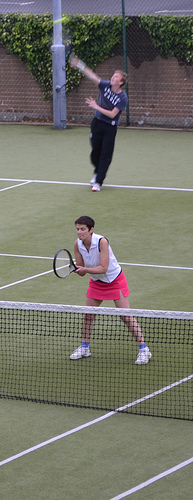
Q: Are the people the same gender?
A: No, they are both male and female.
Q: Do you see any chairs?
A: No, there are no chairs.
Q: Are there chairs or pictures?
A: No, there are no chairs or pictures.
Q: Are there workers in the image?
A: No, there are no workers.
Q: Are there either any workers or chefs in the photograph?
A: No, there are no workers or chefs.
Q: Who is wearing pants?
A: The man is wearing pants.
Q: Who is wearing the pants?
A: The man is wearing pants.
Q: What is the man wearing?
A: The man is wearing trousers.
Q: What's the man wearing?
A: The man is wearing trousers.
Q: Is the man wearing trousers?
A: Yes, the man is wearing trousers.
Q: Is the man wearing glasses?
A: No, the man is wearing trousers.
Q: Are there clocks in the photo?
A: No, there are no clocks.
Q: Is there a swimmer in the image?
A: No, there are no swimmers.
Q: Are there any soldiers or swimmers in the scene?
A: No, there are no swimmers or soldiers.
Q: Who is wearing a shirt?
A: The lady is wearing a shirt.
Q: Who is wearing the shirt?
A: The lady is wearing a shirt.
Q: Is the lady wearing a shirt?
A: Yes, the lady is wearing a shirt.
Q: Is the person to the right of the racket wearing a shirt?
A: Yes, the lady is wearing a shirt.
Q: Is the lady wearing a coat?
A: No, the lady is wearing a shirt.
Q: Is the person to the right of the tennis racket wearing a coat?
A: No, the lady is wearing a shirt.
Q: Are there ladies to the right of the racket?
A: Yes, there is a lady to the right of the racket.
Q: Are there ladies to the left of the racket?
A: No, the lady is to the right of the racket.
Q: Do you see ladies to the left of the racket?
A: No, the lady is to the right of the racket.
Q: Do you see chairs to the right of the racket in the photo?
A: No, there is a lady to the right of the racket.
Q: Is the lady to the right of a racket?
A: Yes, the lady is to the right of a racket.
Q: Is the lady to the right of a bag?
A: No, the lady is to the right of a racket.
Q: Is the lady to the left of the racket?
A: No, the lady is to the right of the racket.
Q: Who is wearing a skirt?
A: The lady is wearing a skirt.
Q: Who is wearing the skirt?
A: The lady is wearing a skirt.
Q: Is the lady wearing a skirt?
A: Yes, the lady is wearing a skirt.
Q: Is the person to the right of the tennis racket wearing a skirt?
A: Yes, the lady is wearing a skirt.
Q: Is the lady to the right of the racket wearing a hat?
A: No, the lady is wearing a skirt.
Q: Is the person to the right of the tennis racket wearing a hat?
A: No, the lady is wearing a skirt.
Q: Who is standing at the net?
A: The lady is standing at the net.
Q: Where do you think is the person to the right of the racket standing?
A: The lady is standing at the net.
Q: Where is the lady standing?
A: The lady is standing at the net.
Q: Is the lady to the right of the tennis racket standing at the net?
A: Yes, the lady is standing at the net.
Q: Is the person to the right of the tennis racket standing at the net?
A: Yes, the lady is standing at the net.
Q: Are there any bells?
A: No, there are no bells.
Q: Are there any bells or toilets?
A: No, there are no bells or toilets.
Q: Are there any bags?
A: No, there are no bags.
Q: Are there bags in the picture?
A: No, there are no bags.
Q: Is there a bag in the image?
A: No, there are no bags.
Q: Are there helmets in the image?
A: No, there are no helmets.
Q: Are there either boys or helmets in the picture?
A: No, there are no helmets or boys.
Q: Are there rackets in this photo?
A: Yes, there is a racket.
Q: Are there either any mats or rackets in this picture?
A: Yes, there is a racket.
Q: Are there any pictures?
A: No, there are no pictures.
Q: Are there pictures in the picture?
A: No, there are no pictures.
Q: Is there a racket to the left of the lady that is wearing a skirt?
A: Yes, there is a racket to the left of the lady.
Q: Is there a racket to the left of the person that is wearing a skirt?
A: Yes, there is a racket to the left of the lady.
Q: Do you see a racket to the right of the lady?
A: No, the racket is to the left of the lady.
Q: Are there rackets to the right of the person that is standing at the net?
A: No, the racket is to the left of the lady.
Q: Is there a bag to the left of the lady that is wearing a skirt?
A: No, there is a racket to the left of the lady.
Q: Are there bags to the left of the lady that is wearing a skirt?
A: No, there is a racket to the left of the lady.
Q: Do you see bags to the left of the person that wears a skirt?
A: No, there is a racket to the left of the lady.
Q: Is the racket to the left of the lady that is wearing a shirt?
A: Yes, the racket is to the left of the lady.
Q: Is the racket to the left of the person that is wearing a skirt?
A: Yes, the racket is to the left of the lady.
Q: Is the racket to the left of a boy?
A: No, the racket is to the left of the lady.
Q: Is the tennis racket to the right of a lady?
A: No, the tennis racket is to the left of a lady.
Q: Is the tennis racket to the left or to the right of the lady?
A: The tennis racket is to the left of the lady.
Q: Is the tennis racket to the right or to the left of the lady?
A: The tennis racket is to the left of the lady.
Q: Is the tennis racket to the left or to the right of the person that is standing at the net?
A: The tennis racket is to the left of the lady.